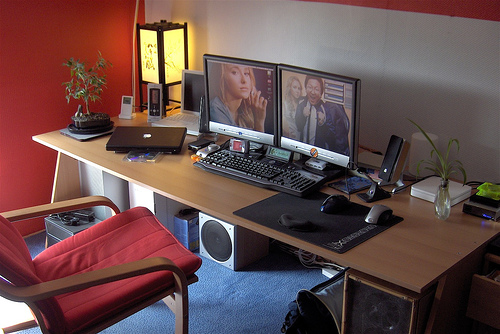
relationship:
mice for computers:
[316, 191, 407, 225] [190, 49, 365, 200]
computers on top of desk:
[190, 49, 365, 200] [153, 159, 193, 192]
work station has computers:
[86, 143, 102, 159] [190, 49, 365, 200]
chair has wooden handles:
[9, 192, 178, 310] [39, 194, 103, 210]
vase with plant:
[434, 185, 452, 218] [407, 113, 473, 190]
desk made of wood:
[153, 159, 193, 192] [112, 167, 150, 181]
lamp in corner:
[136, 12, 188, 81] [141, 6, 149, 19]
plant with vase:
[407, 113, 473, 190] [434, 185, 452, 218]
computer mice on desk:
[324, 192, 381, 229] [153, 159, 193, 192]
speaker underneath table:
[199, 98, 207, 135] [145, 170, 176, 184]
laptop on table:
[109, 114, 186, 157] [145, 170, 176, 184]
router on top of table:
[414, 178, 433, 204] [145, 170, 176, 184]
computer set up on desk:
[174, 70, 203, 132] [153, 159, 193, 192]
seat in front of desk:
[90, 228, 158, 257] [153, 159, 193, 192]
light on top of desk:
[166, 42, 177, 59] [153, 159, 193, 192]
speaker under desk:
[198, 217, 240, 267] [153, 159, 193, 192]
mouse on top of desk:
[366, 203, 395, 234] [153, 159, 193, 192]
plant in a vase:
[407, 113, 473, 190] [434, 185, 452, 218]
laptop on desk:
[109, 114, 186, 157] [153, 159, 193, 192]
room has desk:
[5, 7, 498, 333] [153, 159, 193, 192]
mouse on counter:
[366, 203, 395, 234] [387, 234, 437, 277]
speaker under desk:
[199, 98, 207, 135] [153, 159, 193, 192]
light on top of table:
[166, 42, 177, 59] [145, 170, 176, 184]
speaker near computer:
[199, 98, 207, 135] [174, 70, 203, 132]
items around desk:
[100, 78, 439, 234] [153, 159, 193, 192]